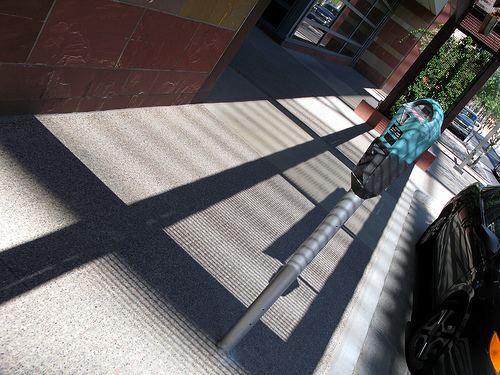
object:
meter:
[359, 74, 426, 213]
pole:
[266, 196, 338, 304]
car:
[429, 197, 477, 316]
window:
[483, 188, 497, 233]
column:
[461, 44, 472, 102]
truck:
[458, 108, 478, 147]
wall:
[72, 12, 142, 81]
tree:
[425, 51, 475, 122]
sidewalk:
[155, 122, 246, 240]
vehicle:
[431, 189, 499, 340]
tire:
[398, 299, 451, 354]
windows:
[301, 14, 349, 49]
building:
[177, 15, 272, 78]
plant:
[415, 47, 476, 103]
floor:
[297, 60, 360, 154]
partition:
[304, 1, 330, 54]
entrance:
[256, 13, 319, 88]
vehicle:
[399, 178, 493, 370]